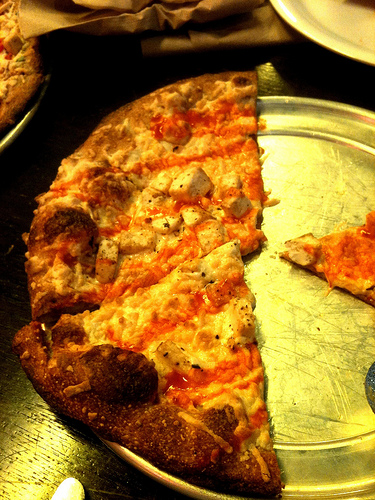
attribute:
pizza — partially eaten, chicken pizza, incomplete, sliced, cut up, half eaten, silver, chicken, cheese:
[11, 69, 374, 498]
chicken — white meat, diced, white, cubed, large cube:
[169, 159, 214, 206]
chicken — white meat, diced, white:
[199, 241, 250, 294]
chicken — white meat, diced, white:
[92, 237, 121, 289]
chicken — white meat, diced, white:
[222, 297, 258, 351]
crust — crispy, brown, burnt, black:
[10, 335, 292, 499]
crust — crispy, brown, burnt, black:
[24, 65, 260, 320]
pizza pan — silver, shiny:
[266, 0, 374, 73]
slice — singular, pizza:
[275, 208, 374, 311]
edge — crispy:
[0, 46, 53, 140]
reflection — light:
[275, 2, 306, 33]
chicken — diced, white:
[220, 183, 254, 223]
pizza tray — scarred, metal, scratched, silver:
[90, 91, 374, 499]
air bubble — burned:
[72, 341, 159, 409]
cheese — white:
[71, 130, 268, 286]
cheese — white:
[81, 244, 272, 446]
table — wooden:
[3, 36, 374, 499]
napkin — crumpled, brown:
[18, 2, 273, 50]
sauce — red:
[150, 108, 263, 146]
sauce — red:
[161, 365, 246, 395]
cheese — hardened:
[62, 380, 94, 401]